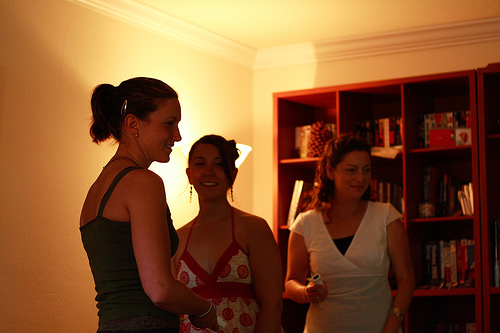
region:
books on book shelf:
[253, 73, 493, 330]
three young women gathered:
[23, 8, 455, 308]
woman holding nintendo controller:
[284, 111, 431, 329]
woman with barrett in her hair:
[85, 63, 206, 330]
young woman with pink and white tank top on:
[153, 124, 313, 326]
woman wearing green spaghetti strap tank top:
[52, 41, 218, 329]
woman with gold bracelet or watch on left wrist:
[282, 125, 446, 324]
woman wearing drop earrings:
[171, 113, 276, 320]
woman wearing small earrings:
[78, 57, 234, 329]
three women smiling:
[48, 59, 499, 331]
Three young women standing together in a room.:
[65, 70, 421, 326]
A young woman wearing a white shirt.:
[280, 130, 410, 330]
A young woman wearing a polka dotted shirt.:
[172, 130, 268, 325]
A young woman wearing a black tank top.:
[75, 76, 195, 326]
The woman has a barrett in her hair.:
[120, 95, 131, 113]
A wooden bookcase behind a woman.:
[263, 77, 498, 328]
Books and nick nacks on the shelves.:
[400, 80, 482, 330]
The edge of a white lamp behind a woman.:
[222, 132, 247, 169]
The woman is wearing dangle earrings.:
[188, 181, 236, 205]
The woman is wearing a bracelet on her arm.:
[387, 301, 407, 321]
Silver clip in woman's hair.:
[120, 95, 157, 140]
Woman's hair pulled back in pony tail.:
[75, 73, 217, 155]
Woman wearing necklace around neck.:
[103, 143, 157, 187]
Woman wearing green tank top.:
[83, 171, 168, 326]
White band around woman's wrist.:
[196, 286, 220, 328]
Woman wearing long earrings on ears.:
[177, 182, 266, 209]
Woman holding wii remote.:
[296, 265, 328, 309]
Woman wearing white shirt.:
[288, 203, 375, 331]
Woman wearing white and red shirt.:
[182, 203, 227, 327]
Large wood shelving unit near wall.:
[256, 80, 493, 311]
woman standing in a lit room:
[5, 37, 422, 331]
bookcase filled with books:
[406, 80, 498, 308]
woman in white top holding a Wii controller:
[276, 132, 412, 332]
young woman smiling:
[171, 133, 303, 331]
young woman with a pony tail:
[76, 74, 191, 331]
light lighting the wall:
[151, 30, 287, 199]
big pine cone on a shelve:
[276, 93, 338, 157]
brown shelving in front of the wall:
[408, 40, 498, 330]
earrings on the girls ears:
[181, 133, 248, 206]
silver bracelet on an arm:
[380, 286, 410, 331]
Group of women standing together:
[81, 88, 432, 329]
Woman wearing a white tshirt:
[279, 183, 408, 329]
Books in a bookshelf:
[402, 152, 477, 227]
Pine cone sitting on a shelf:
[291, 120, 336, 165]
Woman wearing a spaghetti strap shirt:
[165, 220, 237, 329]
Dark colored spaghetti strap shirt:
[83, 172, 174, 327]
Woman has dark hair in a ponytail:
[77, 64, 174, 148]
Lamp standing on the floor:
[208, 106, 259, 164]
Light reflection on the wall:
[243, 37, 339, 110]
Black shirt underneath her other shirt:
[321, 217, 352, 267]